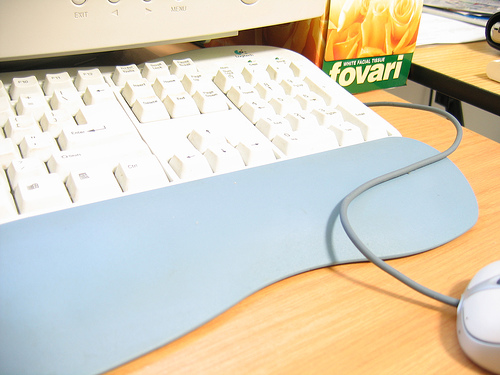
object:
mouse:
[458, 261, 500, 373]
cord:
[333, 101, 463, 306]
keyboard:
[3, 62, 394, 212]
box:
[236, 2, 422, 96]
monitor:
[2, 0, 328, 61]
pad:
[1, 138, 480, 375]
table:
[98, 119, 498, 373]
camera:
[484, 7, 500, 57]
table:
[408, 39, 499, 115]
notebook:
[422, 1, 500, 26]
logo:
[233, 48, 252, 59]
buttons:
[71, 0, 131, 8]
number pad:
[214, 59, 378, 155]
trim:
[408, 59, 500, 120]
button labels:
[68, 5, 201, 25]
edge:
[305, 50, 389, 139]